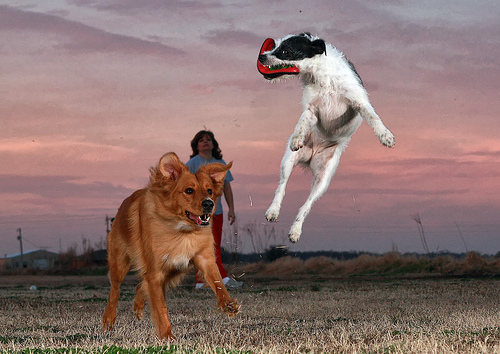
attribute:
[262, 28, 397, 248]
dog — black, jumping, white, playing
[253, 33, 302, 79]
frisbee — red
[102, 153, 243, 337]
dog — brown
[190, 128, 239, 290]
woman — walking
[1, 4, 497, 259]
sky — pink, setting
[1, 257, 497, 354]
grass — dried, dry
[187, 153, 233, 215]
shirt — blue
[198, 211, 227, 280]
pants — red